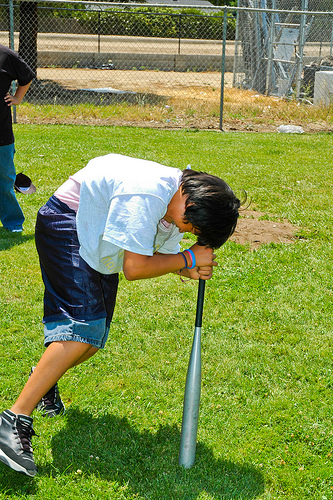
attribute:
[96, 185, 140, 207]
shirt — white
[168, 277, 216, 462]
bat — baseball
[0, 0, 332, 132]
fence — chain link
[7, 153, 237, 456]
kid — frustrated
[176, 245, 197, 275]
bracelets — blue, pink, black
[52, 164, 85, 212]
undershirt — pink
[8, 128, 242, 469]
boy — bent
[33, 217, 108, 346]
short — blue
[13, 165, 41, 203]
hat — brown, black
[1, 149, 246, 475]
boy — young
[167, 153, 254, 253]
hair — dark, long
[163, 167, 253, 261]
hair — black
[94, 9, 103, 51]
pole — metal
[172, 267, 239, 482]
bat — baseball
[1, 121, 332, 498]
grass — green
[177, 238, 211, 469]
bat — gray, black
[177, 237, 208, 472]
bat — aluminum, baseball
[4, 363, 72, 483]
shoes — black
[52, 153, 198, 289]
shirt — light gray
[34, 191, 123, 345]
shorts — blue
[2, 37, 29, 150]
shirt — black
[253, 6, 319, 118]
area — storage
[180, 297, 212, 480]
bat — baseball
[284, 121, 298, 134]
patch — small